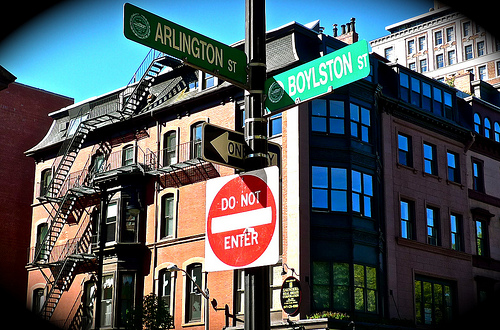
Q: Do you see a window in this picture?
A: Yes, there is a window.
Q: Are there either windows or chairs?
A: Yes, there is a window.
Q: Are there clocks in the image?
A: No, there are no clocks.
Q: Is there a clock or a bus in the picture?
A: No, there are no clocks or buses.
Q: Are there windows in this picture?
A: Yes, there is a window.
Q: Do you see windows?
A: Yes, there is a window.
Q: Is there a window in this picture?
A: Yes, there is a window.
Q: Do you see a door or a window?
A: Yes, there is a window.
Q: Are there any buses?
A: No, there are no buses.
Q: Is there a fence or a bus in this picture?
A: No, there are no buses or fences.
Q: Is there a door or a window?
A: Yes, there is a window.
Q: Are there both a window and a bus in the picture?
A: No, there is a window but no buses.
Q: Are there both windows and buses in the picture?
A: No, there is a window but no buses.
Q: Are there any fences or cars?
A: No, there are no cars or fences.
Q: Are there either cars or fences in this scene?
A: No, there are no cars or fences.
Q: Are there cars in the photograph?
A: No, there are no cars.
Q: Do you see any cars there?
A: No, there are no cars.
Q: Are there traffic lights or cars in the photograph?
A: No, there are no cars or traffic lights.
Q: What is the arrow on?
A: The arrow is on the sign.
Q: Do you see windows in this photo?
A: Yes, there are windows.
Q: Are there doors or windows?
A: Yes, there are windows.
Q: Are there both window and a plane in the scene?
A: No, there are windows but no airplanes.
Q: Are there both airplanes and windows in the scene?
A: No, there are windows but no airplanes.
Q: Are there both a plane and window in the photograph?
A: No, there are windows but no airplanes.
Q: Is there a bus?
A: No, there are no buses.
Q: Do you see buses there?
A: No, there are no buses.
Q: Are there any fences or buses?
A: No, there are no buses or fences.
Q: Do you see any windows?
A: Yes, there is a window.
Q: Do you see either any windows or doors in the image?
A: Yes, there is a window.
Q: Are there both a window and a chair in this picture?
A: No, there is a window but no chairs.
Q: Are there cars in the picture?
A: No, there are no cars.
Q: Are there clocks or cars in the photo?
A: No, there are no cars or clocks.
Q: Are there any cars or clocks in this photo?
A: No, there are no cars or clocks.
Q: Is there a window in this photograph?
A: Yes, there is a window.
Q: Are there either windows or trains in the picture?
A: Yes, there is a window.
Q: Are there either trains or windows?
A: Yes, there is a window.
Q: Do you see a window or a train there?
A: Yes, there is a window.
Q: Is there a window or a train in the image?
A: Yes, there is a window.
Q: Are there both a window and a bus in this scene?
A: No, there is a window but no buses.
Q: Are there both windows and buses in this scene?
A: No, there is a window but no buses.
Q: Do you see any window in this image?
A: Yes, there is a window.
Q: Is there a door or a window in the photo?
A: Yes, there is a window.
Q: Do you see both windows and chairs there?
A: No, there is a window but no chairs.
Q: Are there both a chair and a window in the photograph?
A: No, there is a window but no chairs.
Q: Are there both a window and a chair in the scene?
A: No, there is a window but no chairs.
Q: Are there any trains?
A: No, there are no trains.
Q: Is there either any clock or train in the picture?
A: No, there are no trains or clocks.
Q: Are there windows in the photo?
A: Yes, there is a window.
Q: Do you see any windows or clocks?
A: Yes, there is a window.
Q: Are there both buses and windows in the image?
A: No, there is a window but no buses.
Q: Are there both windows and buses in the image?
A: No, there is a window but no buses.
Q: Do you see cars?
A: No, there are no cars.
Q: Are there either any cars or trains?
A: No, there are no cars or trains.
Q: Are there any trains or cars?
A: No, there are no cars or trains.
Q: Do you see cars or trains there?
A: No, there are no cars or trains.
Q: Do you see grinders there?
A: No, there are no grinders.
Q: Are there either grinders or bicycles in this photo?
A: No, there are no grinders or bicycles.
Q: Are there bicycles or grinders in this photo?
A: No, there are no grinders or bicycles.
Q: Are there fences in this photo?
A: No, there are no fences.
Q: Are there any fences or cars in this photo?
A: No, there are no fences or cars.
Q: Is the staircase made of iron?
A: Yes, the staircase is made of iron.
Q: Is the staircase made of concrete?
A: No, the staircase is made of iron.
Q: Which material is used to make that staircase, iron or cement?
A: The staircase is made of iron.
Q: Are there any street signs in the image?
A: Yes, there is a street sign.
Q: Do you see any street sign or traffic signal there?
A: Yes, there is a street sign.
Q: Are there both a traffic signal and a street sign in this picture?
A: No, there is a street sign but no traffic lights.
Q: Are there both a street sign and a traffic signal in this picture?
A: No, there is a street sign but no traffic lights.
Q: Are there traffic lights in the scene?
A: No, there are no traffic lights.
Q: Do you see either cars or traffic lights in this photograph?
A: No, there are no traffic lights or cars.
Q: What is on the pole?
A: The street sign is on the pole.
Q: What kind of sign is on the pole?
A: The sign is a street sign.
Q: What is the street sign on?
A: The street sign is on the pole.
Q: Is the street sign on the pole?
A: Yes, the street sign is on the pole.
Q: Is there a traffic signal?
A: No, there are no traffic lights.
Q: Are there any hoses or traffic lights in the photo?
A: No, there are no traffic lights or hoses.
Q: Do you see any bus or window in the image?
A: Yes, there is a window.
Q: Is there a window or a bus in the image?
A: Yes, there is a window.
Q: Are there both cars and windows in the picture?
A: No, there is a window but no cars.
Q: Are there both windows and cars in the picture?
A: No, there is a window but no cars.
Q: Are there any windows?
A: Yes, there is a window.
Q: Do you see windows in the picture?
A: Yes, there is a window.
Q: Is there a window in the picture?
A: Yes, there is a window.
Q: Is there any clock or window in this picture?
A: Yes, there is a window.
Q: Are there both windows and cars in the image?
A: No, there is a window but no cars.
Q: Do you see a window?
A: Yes, there is a window.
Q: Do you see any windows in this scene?
A: Yes, there is a window.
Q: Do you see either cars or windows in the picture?
A: Yes, there is a window.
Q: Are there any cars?
A: No, there are no cars.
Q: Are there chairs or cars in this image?
A: No, there are no cars or chairs.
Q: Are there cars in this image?
A: No, there are no cars.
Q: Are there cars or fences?
A: No, there are no cars or fences.